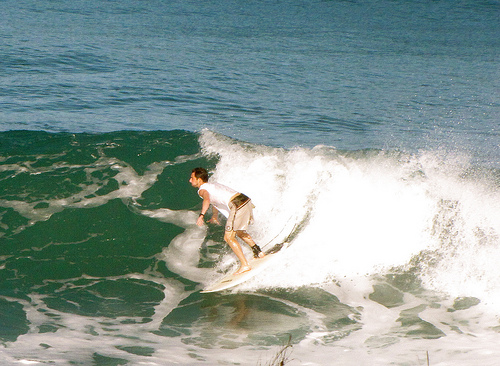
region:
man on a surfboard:
[176, 163, 284, 277]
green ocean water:
[25, 158, 155, 263]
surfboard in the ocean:
[199, 275, 248, 302]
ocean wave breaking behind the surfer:
[234, 134, 406, 222]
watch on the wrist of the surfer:
[196, 205, 209, 219]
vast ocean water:
[131, 28, 406, 108]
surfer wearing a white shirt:
[200, 182, 235, 207]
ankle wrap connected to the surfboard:
[241, 243, 264, 254]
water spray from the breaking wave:
[399, 120, 480, 180]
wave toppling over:
[11, 119, 167, 189]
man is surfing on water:
[173, 171, 251, 277]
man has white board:
[211, 239, 309, 315]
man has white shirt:
[201, 159, 228, 214]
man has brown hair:
[186, 161, 205, 192]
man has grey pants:
[221, 188, 266, 285]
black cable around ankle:
[246, 234, 261, 265]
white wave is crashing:
[213, 156, 441, 355]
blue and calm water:
[101, 58, 401, 121]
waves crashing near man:
[76, 136, 412, 364]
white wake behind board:
[268, 163, 339, 265]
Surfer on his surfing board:
[185, 166, 302, 295]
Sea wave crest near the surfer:
[205, 131, 499, 298]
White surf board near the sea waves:
[192, 233, 306, 294]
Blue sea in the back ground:
[0, 5, 495, 127]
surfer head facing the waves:
[184, 165, 209, 190]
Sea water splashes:
[386, 103, 488, 170]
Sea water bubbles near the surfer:
[15, 301, 152, 359]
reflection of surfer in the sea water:
[195, 291, 263, 341]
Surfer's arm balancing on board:
[192, 188, 214, 223]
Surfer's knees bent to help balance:
[219, 229, 236, 246]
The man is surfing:
[172, 158, 314, 306]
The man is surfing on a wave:
[160, 127, 401, 304]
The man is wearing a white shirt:
[179, 158, 249, 212]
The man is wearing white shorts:
[221, 196, 262, 237]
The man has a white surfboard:
[191, 247, 278, 294]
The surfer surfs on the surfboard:
[148, 140, 318, 303]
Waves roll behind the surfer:
[33, 110, 475, 322]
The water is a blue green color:
[20, 15, 196, 277]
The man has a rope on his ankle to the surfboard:
[245, 237, 275, 262]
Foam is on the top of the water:
[264, 153, 456, 298]